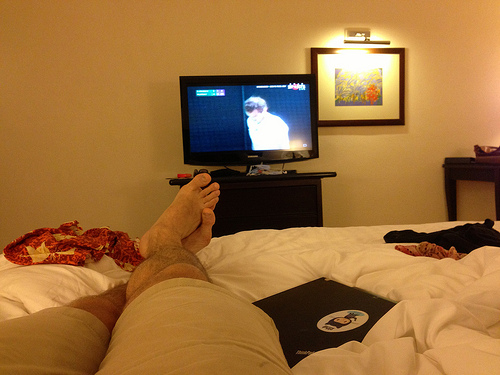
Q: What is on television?
A: Tennis match.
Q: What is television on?
A: Stand.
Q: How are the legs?
A: Hairy.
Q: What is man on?
A: Bed.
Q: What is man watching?
A: Television.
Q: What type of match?
A: Tennis.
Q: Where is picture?
A: On wall.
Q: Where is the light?
A: Picture frame.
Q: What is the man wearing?
A: Beige shorts.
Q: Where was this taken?
A: Bedroom.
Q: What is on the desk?
A: TV.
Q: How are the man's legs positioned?
A: Crossed.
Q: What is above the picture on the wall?
A: Light.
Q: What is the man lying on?
A: Bed.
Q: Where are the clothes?
A: End of bed.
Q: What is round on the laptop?
A: Sticker.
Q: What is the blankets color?
A: White.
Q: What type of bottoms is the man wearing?
A: Shorts.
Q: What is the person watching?
A: A television.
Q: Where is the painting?
A: On the wall.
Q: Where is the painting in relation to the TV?
A: To the right.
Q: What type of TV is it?
A: Flat screen.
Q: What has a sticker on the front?
A: A laptop.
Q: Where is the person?
A: On a bed.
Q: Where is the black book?
A: On the bed.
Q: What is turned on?
A: Tv.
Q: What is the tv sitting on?
A: Table.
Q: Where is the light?
A: Over picture.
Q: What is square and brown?
A: Picture frame.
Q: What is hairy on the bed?
A: Legs.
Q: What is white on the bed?
A: Comforter.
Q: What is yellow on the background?
A: Walls.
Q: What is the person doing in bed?
A: Watching tv.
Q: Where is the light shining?
A: Over the picture on the wall.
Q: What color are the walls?
A: Beige.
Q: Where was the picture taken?
A: In a bedroom.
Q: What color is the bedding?
A: White.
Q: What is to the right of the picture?
A: A table.